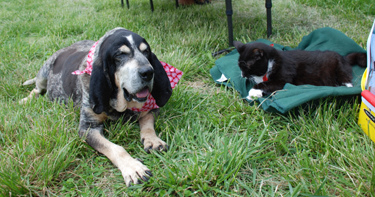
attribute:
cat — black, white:
[237, 40, 373, 103]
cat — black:
[231, 38, 369, 110]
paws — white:
[242, 82, 269, 105]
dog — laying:
[25, 26, 170, 181]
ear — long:
[89, 47, 112, 115]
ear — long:
[144, 51, 170, 102]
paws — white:
[247, 88, 261, 101]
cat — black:
[229, 33, 365, 100]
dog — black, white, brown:
[19, 20, 168, 185]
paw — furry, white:
[233, 78, 304, 130]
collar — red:
[261, 42, 274, 81]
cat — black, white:
[225, 23, 334, 100]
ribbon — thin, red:
[252, 56, 275, 85]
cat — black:
[229, 32, 368, 95]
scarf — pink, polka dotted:
[70, 38, 185, 113]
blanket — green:
[205, 24, 367, 112]